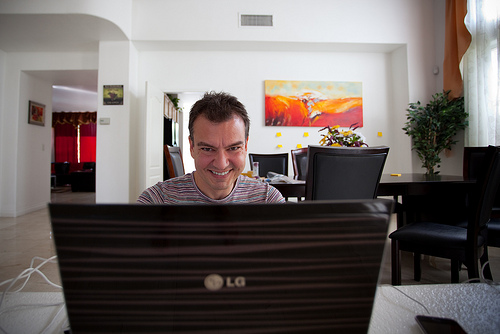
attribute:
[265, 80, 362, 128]
painting — large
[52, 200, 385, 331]
laptop — lg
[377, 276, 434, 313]
cable — white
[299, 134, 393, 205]
chair — black, empty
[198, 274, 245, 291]
logo — LG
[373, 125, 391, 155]
sticker — yellow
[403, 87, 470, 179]
plant — green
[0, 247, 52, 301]
cables — white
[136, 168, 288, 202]
shirt — striped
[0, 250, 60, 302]
cable — long, white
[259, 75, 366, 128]
picture — orange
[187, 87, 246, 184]
man — smiling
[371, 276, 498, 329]
table — white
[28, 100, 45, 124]
picture — hanging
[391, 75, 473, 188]
plant — small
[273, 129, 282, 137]
sticker — yellow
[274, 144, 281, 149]
sticker — yellow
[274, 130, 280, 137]
sticker — yellow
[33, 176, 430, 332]
laptop — black, glossy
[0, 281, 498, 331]
table — white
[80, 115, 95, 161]
curtain — red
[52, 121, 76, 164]
curtain — red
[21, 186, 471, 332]
table — grey